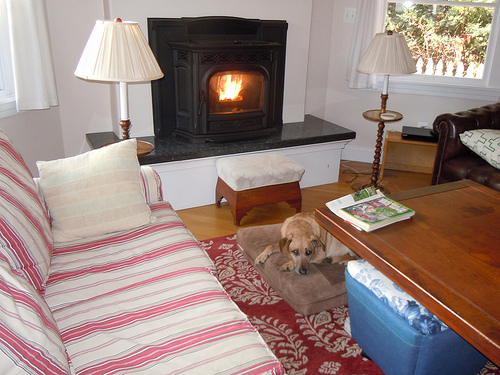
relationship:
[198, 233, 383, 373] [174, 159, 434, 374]
rug on floor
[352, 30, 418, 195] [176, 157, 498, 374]
lamp on floor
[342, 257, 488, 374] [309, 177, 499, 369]
container under table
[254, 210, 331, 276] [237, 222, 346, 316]
dog on pillow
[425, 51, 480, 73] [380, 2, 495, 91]
fence on window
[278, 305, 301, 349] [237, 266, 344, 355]
part of a carpet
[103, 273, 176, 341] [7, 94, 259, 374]
part of a cushion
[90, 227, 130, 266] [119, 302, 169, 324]
part of a line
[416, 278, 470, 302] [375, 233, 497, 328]
part of a line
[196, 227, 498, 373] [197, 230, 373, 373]
carpet has white flowers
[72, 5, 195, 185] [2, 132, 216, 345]
lamp beside couch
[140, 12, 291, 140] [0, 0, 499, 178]
fireplace in wall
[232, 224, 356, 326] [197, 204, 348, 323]
cushion on floor